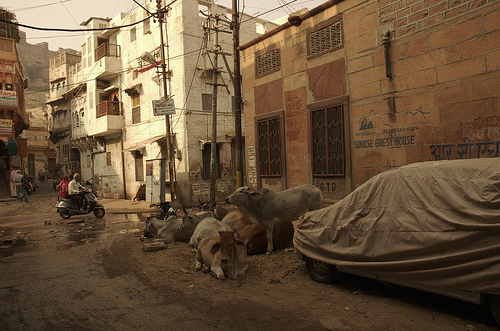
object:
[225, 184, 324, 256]
cow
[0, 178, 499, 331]
road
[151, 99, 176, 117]
sign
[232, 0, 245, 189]
pole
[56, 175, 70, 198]
shirt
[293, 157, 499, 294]
cover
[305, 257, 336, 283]
tire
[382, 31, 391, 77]
pipe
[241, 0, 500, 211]
wall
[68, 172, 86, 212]
man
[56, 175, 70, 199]
women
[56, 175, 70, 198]
outfit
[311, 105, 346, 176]
fence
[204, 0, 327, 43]
line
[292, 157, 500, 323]
car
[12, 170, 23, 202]
men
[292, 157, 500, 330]
vehicle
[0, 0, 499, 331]
city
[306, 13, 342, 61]
window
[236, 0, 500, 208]
building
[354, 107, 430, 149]
writing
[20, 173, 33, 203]
people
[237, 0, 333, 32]
awning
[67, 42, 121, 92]
balcony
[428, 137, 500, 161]
graffiti